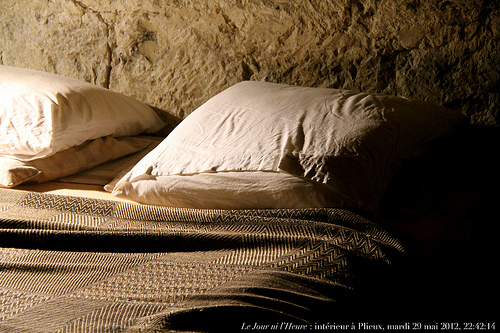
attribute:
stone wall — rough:
[2, 2, 494, 172]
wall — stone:
[3, 2, 498, 108]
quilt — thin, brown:
[65, 204, 437, 314]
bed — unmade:
[74, 131, 348, 308]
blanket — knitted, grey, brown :
[0, 190, 410, 330]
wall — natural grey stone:
[3, 2, 492, 129]